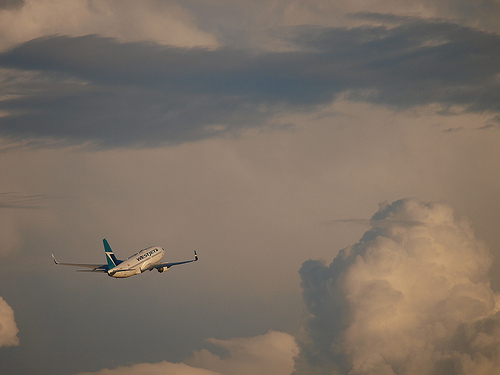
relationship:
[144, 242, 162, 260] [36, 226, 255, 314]
letter on plane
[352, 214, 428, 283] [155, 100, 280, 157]
cloud in sky